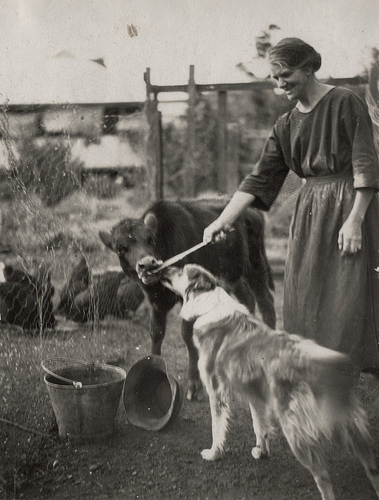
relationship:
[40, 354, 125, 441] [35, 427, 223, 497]
bucket on ground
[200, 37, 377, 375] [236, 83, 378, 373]
woman in a dress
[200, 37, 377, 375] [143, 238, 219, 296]
woman hold a stick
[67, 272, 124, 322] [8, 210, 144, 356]
chicken in a coop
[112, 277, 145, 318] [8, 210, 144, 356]
chicken in a coop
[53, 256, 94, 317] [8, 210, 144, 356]
chicken in a coop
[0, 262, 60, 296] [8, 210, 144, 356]
chicken in a coop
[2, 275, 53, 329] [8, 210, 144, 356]
chicken in a coop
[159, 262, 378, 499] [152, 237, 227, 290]
animals licking a stick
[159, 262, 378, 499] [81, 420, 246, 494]
animals in yard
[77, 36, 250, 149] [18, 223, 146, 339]
fence made of chicken wire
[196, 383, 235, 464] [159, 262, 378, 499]
leg of animals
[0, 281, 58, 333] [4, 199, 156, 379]
chicken in yard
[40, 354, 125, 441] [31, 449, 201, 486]
bucket on ground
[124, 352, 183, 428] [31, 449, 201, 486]
hat on ground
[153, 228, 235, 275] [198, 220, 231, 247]
stick on hand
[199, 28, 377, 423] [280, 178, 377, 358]
woman wears dress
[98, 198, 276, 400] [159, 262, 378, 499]
calf next animals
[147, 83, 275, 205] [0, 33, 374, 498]
wooden chicken in farm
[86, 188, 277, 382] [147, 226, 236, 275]
calf licking spoon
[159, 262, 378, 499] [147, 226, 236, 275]
animals licking spoon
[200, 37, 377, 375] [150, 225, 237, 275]
woman holds spoon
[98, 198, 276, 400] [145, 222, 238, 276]
calf liking spoon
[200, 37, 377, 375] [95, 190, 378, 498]
woman next animals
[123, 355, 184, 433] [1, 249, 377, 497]
hat on ground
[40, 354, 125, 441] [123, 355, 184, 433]
bucket next hat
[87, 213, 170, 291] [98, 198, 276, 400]
head of calf